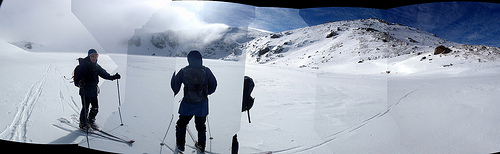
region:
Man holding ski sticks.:
[112, 61, 123, 129]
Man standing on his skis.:
[65, 45, 135, 142]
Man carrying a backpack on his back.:
[70, 51, 87, 93]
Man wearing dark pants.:
[70, 85, 107, 135]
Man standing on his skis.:
[160, 46, 215, 151]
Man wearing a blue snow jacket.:
[175, 59, 215, 122]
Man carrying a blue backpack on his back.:
[180, 62, 213, 104]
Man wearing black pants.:
[170, 111, 211, 146]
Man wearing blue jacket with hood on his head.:
[170, 45, 215, 113]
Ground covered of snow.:
[255, 52, 477, 145]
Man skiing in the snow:
[35, 9, 227, 143]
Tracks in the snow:
[314, 81, 424, 151]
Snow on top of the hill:
[287, 8, 433, 54]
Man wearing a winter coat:
[154, 60, 239, 148]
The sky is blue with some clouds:
[407, 13, 499, 55]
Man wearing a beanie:
[79, 47, 99, 53]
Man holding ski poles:
[65, 82, 110, 123]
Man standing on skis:
[67, 110, 145, 152]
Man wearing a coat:
[70, 53, 132, 134]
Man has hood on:
[177, 34, 232, 94]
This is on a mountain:
[32, 9, 446, 146]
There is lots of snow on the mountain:
[291, 12, 480, 103]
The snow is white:
[281, 24, 496, 144]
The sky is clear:
[292, 11, 477, 58]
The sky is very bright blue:
[315, 7, 497, 27]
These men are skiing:
[45, 51, 225, 141]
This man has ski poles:
[57, 52, 144, 138]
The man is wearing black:
[60, 55, 145, 135]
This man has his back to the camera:
[163, 47, 236, 147]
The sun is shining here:
[117, 2, 234, 53]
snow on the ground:
[288, 79, 360, 134]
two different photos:
[33, 13, 438, 141]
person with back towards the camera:
[160, 40, 234, 118]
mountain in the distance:
[341, 14, 397, 56]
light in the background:
[172, 8, 210, 25]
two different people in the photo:
[56, 41, 218, 115]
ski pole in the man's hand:
[161, 106, 183, 128]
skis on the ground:
[104, 120, 136, 150]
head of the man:
[83, 45, 103, 72]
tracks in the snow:
[22, 75, 54, 115]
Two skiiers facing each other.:
[50, 35, 225, 152]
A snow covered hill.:
[258, 13, 438, 73]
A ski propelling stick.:
[114, 77, 132, 130]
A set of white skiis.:
[58, 115, 137, 150]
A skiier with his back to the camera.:
[158, 46, 219, 152]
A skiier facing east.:
[59, 43, 137, 147]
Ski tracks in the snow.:
[0, 60, 48, 143]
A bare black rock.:
[430, 42, 456, 57]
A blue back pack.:
[241, 70, 265, 114]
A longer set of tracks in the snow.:
[288, 76, 433, 152]